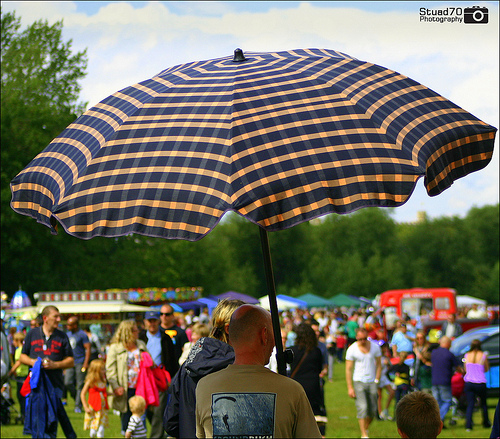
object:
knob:
[233, 47, 243, 63]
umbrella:
[8, 46, 498, 374]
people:
[344, 325, 387, 438]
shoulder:
[273, 372, 304, 397]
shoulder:
[194, 372, 226, 392]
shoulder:
[24, 327, 35, 339]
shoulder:
[347, 341, 357, 353]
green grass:
[331, 410, 353, 436]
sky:
[196, 1, 398, 16]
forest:
[0, 204, 499, 294]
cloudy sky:
[0, 2, 93, 30]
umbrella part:
[50, 61, 235, 242]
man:
[11, 302, 84, 437]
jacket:
[20, 352, 68, 437]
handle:
[256, 229, 291, 373]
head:
[227, 304, 276, 365]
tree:
[1, 3, 96, 298]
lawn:
[272, 315, 467, 435]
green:
[484, 232, 496, 249]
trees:
[0, 10, 92, 299]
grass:
[327, 360, 353, 379]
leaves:
[303, 218, 399, 286]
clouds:
[129, 0, 186, 48]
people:
[322, 316, 346, 378]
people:
[157, 301, 192, 366]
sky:
[57, 0, 134, 44]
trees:
[302, 250, 380, 300]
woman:
[106, 321, 161, 435]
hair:
[109, 318, 136, 347]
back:
[193, 366, 326, 439]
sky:
[452, 60, 495, 94]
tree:
[195, 227, 252, 295]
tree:
[279, 214, 349, 296]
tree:
[342, 205, 402, 297]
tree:
[395, 213, 465, 290]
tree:
[449, 204, 500, 304]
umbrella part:
[255, 221, 290, 370]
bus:
[370, 288, 467, 330]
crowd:
[15, 290, 499, 438]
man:
[194, 304, 323, 438]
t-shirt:
[191, 365, 328, 437]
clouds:
[427, 27, 497, 75]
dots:
[323, 157, 352, 178]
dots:
[168, 153, 202, 172]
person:
[385, 318, 413, 360]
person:
[431, 332, 459, 421]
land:
[1, 319, 500, 439]